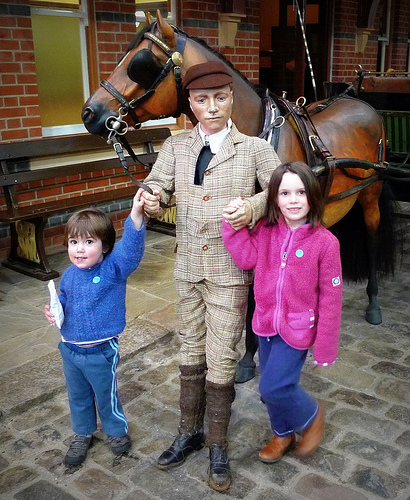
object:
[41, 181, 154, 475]
boy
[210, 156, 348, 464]
children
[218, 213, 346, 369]
jacket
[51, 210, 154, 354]
sweater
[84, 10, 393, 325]
horse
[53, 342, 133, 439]
pants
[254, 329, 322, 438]
pants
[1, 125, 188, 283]
bench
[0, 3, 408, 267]
building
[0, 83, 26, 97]
brick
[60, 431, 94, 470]
shoe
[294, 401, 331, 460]
shoe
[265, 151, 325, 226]
head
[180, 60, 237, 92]
hat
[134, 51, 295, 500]
statue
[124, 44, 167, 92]
patch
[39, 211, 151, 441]
blue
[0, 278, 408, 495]
street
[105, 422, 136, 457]
shoes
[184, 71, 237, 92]
bill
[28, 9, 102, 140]
glass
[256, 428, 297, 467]
shoe